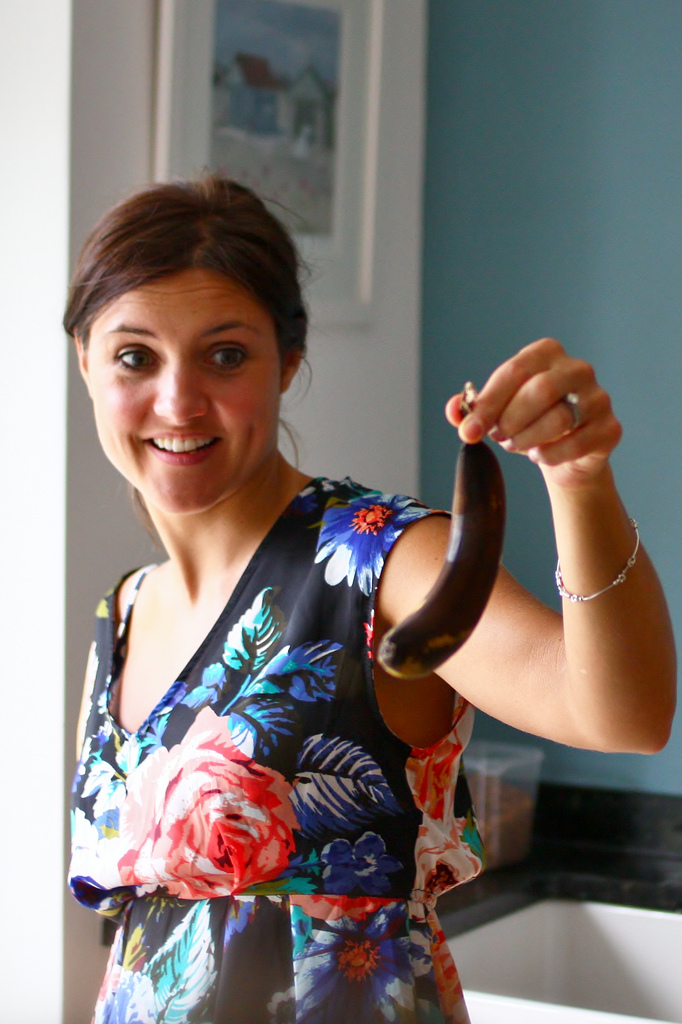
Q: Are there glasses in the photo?
A: No, there are no glasses.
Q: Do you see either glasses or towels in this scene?
A: No, there are no glasses or towels.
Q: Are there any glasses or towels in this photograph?
A: No, there are no glasses or towels.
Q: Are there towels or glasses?
A: No, there are no glasses or towels.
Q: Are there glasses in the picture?
A: No, there are no glasses.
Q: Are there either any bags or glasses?
A: No, there are no glasses or bags.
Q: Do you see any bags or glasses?
A: No, there are no glasses or bags.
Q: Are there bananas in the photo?
A: Yes, there is a banana.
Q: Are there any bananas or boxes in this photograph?
A: Yes, there is a banana.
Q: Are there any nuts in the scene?
A: No, there are no nuts.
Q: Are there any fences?
A: No, there are no fences.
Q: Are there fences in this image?
A: No, there are no fences.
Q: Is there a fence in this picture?
A: No, there are no fences.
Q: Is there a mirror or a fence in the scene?
A: No, there are no fences or mirrors.